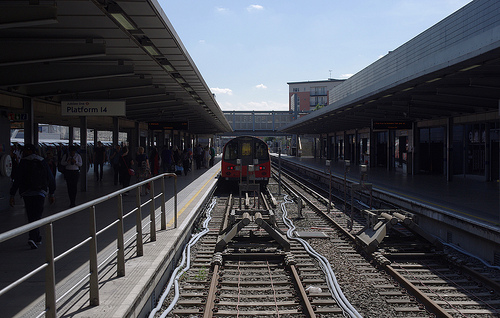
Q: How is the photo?
A: Clear.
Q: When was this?
A: Daytime.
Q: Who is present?
A: People.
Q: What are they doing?
A: Walking.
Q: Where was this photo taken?
A: In a train station.